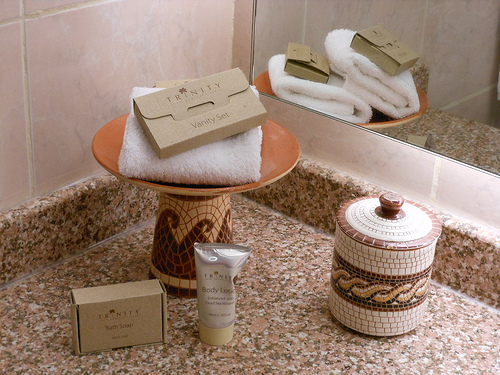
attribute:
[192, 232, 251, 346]
tube — squeezed, upside down, beauty cream, lotion, silver, yellow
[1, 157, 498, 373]
counter — marbled, brown, speckled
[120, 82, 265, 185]
towel — white, folded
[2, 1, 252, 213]
wall — tiled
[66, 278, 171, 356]
box — brown, little, cardboard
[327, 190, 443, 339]
container — brown, white, round, ceramic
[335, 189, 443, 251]
cover — brown, white, round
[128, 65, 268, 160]
box — small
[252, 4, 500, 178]
mirror — on the right